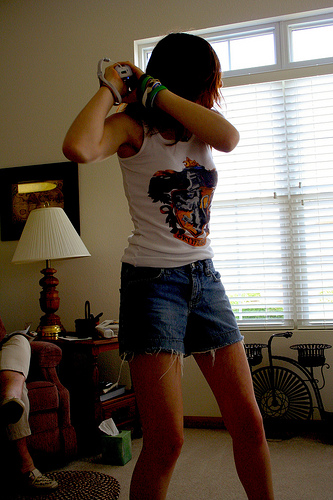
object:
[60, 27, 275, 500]
girl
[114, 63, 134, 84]
remote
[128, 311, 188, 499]
leg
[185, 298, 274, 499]
leg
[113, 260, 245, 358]
shorts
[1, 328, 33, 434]
legs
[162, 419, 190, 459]
knee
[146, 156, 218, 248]
design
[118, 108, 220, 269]
shirt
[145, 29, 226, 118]
hair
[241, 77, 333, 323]
blinds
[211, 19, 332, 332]
window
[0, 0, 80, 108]
wall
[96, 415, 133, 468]
tissue box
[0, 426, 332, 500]
floor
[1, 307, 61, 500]
woman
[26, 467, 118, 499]
rug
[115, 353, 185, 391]
strings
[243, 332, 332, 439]
decoration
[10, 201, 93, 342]
lamp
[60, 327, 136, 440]
table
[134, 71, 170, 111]
bracelets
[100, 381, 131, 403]
book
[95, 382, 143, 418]
shelf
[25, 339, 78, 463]
sofa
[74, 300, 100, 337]
basket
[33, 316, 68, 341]
brass base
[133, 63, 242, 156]
arm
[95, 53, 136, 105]
video game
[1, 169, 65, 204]
poster